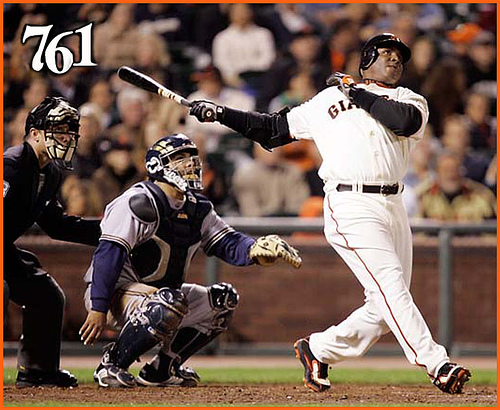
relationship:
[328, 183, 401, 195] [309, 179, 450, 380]
belt on pants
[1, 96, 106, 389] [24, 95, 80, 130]
men wearing helmet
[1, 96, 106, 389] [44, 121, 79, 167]
men wearing face mask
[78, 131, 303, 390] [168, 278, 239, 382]
catcher wearing leg guards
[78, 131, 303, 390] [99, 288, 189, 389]
catcher wearing leg guards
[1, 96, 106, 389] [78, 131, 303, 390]
men behind catcher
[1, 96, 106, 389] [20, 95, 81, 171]
men wearing helmets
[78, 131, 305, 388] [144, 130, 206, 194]
catcher wearing helmets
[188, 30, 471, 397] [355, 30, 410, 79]
men wearing helmets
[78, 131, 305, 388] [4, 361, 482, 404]
catcher crouching by ground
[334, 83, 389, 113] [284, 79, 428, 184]
lettering on shirt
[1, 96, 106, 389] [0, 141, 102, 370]
men wearing uniform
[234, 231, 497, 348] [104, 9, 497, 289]
wall of stadium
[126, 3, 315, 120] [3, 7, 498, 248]
spectators sitting in stands